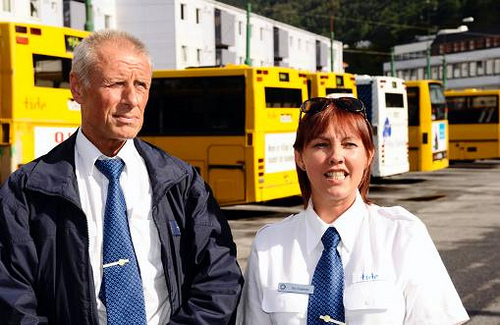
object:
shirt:
[235, 188, 471, 324]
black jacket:
[0, 126, 247, 324]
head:
[68, 29, 154, 140]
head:
[292, 100, 375, 202]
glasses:
[297, 96, 369, 120]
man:
[0, 27, 245, 324]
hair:
[293, 99, 376, 211]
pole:
[243, 1, 253, 65]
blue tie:
[305, 225, 349, 324]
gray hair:
[69, 30, 154, 92]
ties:
[93, 157, 147, 325]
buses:
[403, 79, 449, 173]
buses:
[441, 88, 499, 166]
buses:
[140, 63, 310, 207]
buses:
[0, 19, 92, 180]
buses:
[307, 71, 358, 98]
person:
[236, 97, 473, 325]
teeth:
[334, 172, 341, 177]